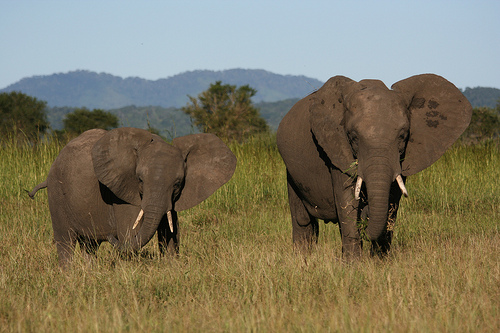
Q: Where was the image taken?
A: It was taken at the field.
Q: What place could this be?
A: It is a field.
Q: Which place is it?
A: It is a field.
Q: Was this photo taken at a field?
A: Yes, it was taken in a field.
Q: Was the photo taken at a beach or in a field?
A: It was taken at a field.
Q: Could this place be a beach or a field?
A: It is a field.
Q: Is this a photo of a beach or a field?
A: It is showing a field.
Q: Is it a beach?
A: No, it is a field.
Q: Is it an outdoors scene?
A: Yes, it is outdoors.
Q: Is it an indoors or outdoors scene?
A: It is outdoors.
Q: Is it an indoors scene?
A: No, it is outdoors.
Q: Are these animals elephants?
A: Yes, all the animals are elephants.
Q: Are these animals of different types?
A: No, all the animals are elephants.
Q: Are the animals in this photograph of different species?
A: No, all the animals are elephants.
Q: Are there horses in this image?
A: No, there are no horses.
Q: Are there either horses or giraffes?
A: No, there are no horses or giraffes.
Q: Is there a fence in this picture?
A: No, there are no fences.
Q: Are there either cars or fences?
A: No, there are no fences or cars.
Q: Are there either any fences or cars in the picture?
A: No, there are no fences or cars.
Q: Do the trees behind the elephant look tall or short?
A: The trees are tall.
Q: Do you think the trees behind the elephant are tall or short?
A: The trees are tall.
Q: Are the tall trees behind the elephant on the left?
A: Yes, the trees are behind the elephant.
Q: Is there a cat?
A: No, there are no cats.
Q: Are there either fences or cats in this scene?
A: No, there are no cats or fences.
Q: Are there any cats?
A: No, there are no cats.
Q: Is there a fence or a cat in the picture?
A: No, there are no cats or fences.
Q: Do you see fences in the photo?
A: No, there are no fences.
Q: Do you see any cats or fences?
A: No, there are no fences or cats.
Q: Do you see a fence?
A: No, there are no fences.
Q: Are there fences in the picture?
A: No, there are no fences.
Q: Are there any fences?
A: No, there are no fences.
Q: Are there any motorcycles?
A: No, there are no motorcycles.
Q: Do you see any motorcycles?
A: No, there are no motorcycles.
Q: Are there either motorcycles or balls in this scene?
A: No, there are no motorcycles or balls.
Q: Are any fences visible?
A: No, there are no fences.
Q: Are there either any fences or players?
A: No, there are no fences or players.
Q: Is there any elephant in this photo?
A: Yes, there is an elephant.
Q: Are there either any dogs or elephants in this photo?
A: Yes, there is an elephant.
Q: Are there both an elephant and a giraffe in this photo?
A: No, there is an elephant but no giraffes.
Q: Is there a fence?
A: No, there are no fences.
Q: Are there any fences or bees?
A: No, there are no fences or bees.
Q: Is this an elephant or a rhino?
A: This is an elephant.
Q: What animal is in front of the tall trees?
A: The elephant is in front of the trees.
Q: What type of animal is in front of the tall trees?
A: The animal is an elephant.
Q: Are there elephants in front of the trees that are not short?
A: Yes, there is an elephant in front of the trees.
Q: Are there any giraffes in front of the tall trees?
A: No, there is an elephant in front of the trees.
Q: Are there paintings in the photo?
A: No, there are no paintings.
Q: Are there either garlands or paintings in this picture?
A: No, there are no paintings or garlands.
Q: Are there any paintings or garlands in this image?
A: No, there are no paintings or garlands.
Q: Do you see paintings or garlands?
A: No, there are no paintings or garlands.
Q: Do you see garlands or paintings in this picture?
A: No, there are no paintings or garlands.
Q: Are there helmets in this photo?
A: No, there are no helmets.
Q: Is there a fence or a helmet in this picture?
A: No, there are no helmets or fences.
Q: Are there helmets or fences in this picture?
A: No, there are no helmets or fences.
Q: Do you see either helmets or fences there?
A: No, there are no helmets or fences.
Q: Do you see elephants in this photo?
A: Yes, there is an elephant.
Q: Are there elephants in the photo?
A: Yes, there is an elephant.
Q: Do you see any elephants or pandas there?
A: Yes, there is an elephant.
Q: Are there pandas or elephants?
A: Yes, there is an elephant.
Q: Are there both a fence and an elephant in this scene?
A: No, there is an elephant but no fences.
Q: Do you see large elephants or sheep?
A: Yes, there is a large elephant.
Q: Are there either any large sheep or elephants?
A: Yes, there is a large elephant.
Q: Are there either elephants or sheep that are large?
A: Yes, the elephant is large.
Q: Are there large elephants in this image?
A: Yes, there is a large elephant.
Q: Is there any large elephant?
A: Yes, there is a large elephant.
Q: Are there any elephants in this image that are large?
A: Yes, there is an elephant that is large.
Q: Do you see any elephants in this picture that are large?
A: Yes, there is an elephant that is large.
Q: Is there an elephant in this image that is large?
A: Yes, there is an elephant that is large.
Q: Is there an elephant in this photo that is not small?
A: Yes, there is a large elephant.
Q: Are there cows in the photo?
A: No, there are no cows.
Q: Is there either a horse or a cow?
A: No, there are no cows or horses.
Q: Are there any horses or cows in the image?
A: No, there are no cows or horses.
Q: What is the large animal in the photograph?
A: The animal is an elephant.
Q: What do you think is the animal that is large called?
A: The animal is an elephant.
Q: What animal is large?
A: The animal is an elephant.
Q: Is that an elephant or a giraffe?
A: That is an elephant.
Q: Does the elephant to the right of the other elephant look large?
A: Yes, the elephant is large.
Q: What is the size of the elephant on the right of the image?
A: The elephant is large.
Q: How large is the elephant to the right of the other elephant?
A: The elephant is large.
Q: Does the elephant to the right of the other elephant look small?
A: No, the elephant is large.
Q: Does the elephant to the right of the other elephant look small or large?
A: The elephant is large.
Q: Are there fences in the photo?
A: No, there are no fences.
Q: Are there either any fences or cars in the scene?
A: No, there are no fences or cars.